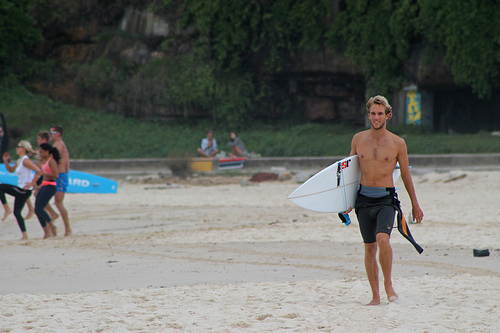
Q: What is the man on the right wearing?
A: Wet suit.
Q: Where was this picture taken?
A: On the beach.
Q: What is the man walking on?
A: Sand.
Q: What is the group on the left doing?
A: Exerising.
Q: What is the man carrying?
A: A surfboard.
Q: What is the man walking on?
A: The beach.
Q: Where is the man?
A: At the beach.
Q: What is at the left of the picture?
A: A group of people.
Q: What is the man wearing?
A: A wet suit.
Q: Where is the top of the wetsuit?
A: Pulled down.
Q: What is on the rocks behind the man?
A: Vines.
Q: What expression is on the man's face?
A: A smile.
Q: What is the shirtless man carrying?
A: Surfboard.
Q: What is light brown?
A: Sand.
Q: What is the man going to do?
A: Surf.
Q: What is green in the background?
A: Trees.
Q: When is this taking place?
A: Daytime.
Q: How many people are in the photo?
A: Seven.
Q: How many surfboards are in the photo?
A: Two.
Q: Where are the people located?
A: Beach.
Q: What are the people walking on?
A: Sand.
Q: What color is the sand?
A: Tan.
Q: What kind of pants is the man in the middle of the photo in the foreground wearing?
A: Shorts.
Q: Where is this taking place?
A: On the beach.